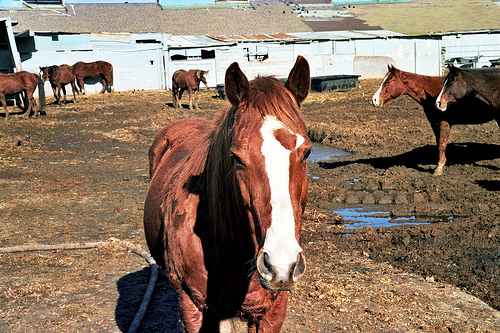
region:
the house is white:
[232, 17, 372, 82]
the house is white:
[295, 2, 377, 90]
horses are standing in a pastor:
[18, 13, 486, 245]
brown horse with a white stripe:
[148, 80, 347, 317]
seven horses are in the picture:
[5, 29, 487, 332]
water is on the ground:
[336, 171, 450, 280]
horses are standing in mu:
[315, 62, 495, 299]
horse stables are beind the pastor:
[26, 7, 455, 74]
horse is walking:
[36, 59, 79, 106]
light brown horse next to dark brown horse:
[367, 50, 495, 116]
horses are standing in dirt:
[24, 62, 486, 319]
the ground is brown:
[28, 131, 373, 332]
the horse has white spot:
[195, 105, 322, 275]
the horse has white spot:
[233, 108, 310, 242]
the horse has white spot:
[236, 47, 313, 207]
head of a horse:
[245, 94, 277, 151]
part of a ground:
[48, 264, 103, 313]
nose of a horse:
[238, 234, 302, 281]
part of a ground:
[368, 159, 411, 196]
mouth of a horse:
[365, 87, 407, 124]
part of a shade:
[148, 286, 175, 324]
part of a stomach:
[140, 170, 175, 214]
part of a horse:
[250, 80, 295, 120]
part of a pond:
[318, 130, 364, 167]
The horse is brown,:
[130, 40, 351, 331]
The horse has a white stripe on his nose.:
[247, 100, 308, 290]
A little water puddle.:
[325, 198, 437, 240]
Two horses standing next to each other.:
[360, 41, 497, 157]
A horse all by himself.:
[150, 60, 206, 115]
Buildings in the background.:
[1, 0, 496, 85]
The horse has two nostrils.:
[245, 231, 323, 286]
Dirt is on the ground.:
[12, 132, 128, 233]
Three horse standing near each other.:
[1, 51, 116, 117]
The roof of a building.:
[69, 0, 166, 39]